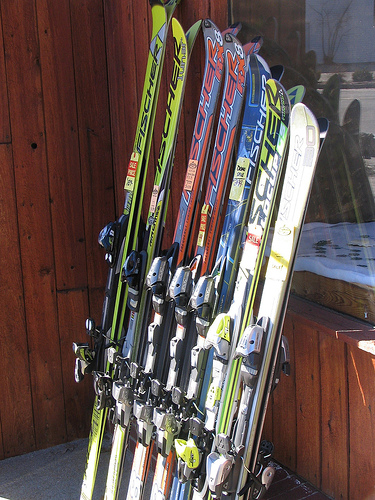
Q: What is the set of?
A: Skis.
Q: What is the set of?
A: Skis.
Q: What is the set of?
A: Skis.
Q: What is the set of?
A: Skis.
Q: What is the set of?
A: Skis.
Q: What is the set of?
A: Skis.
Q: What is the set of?
A: Skis.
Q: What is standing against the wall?
A: Skis.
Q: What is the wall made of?
A: Wood.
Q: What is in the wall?
A: Window.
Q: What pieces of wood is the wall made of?
A: Wood panels.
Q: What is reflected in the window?
A: Skis.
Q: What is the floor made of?
A: Carpet.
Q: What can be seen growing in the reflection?
A: Tree.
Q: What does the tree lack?
A: Leaves.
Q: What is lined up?
A: Boot binding.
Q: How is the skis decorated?
A: Colorful logos.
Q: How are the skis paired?
A: In sets.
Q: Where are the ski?
A: Leaning on building.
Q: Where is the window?
A: Side of building.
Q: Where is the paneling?
A: On wall.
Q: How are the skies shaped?
A: Tall and thin.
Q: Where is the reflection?
A: Window.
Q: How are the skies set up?
A: In pairs.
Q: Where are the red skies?
A: Wall.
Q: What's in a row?
A: Skis.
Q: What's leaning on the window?
A: Skis.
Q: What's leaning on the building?
A: Skis.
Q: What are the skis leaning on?
A: Window.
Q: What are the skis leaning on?
A: Building.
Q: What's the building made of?
A: Wood planks.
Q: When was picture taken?
A: Daytime.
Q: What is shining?
A: Sun.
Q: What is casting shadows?
A: Displays.